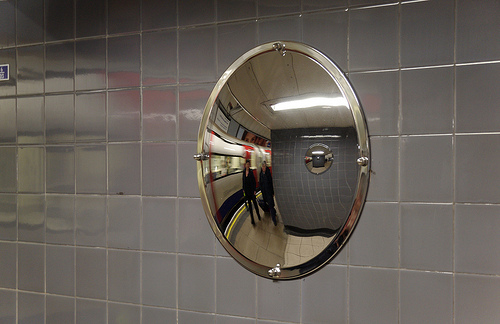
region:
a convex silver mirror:
[182, 35, 379, 284]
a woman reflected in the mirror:
[240, 152, 260, 233]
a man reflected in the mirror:
[258, 156, 280, 231]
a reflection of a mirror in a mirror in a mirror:
[301, 135, 341, 177]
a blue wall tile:
[91, 77, 150, 149]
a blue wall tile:
[397, 194, 459, 279]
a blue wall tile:
[71, 83, 106, 148]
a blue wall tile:
[95, 235, 150, 315]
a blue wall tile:
[7, 231, 53, 303]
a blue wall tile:
[338, 1, 410, 73]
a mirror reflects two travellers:
[193, 37, 373, 283]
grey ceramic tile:
[6, 90, 196, 318]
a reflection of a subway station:
[193, 37, 372, 282]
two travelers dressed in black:
[240, 157, 280, 225]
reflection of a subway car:
[196, 56, 243, 268]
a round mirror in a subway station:
[194, 39, 374, 282]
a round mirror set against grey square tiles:
[177, 27, 418, 305]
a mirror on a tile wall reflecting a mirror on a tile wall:
[266, 116, 371, 284]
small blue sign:
[0, 62, 7, 81]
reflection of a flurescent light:
[262, 92, 345, 110]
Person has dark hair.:
[241, 155, 252, 170]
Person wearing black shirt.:
[228, 168, 265, 191]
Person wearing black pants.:
[241, 196, 268, 230]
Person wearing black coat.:
[255, 180, 271, 185]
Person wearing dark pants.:
[261, 203, 284, 214]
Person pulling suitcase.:
[251, 189, 267, 216]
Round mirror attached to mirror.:
[210, 87, 324, 213]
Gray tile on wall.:
[402, 208, 461, 307]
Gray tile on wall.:
[351, 263, 392, 307]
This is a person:
[234, 147, 266, 233]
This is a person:
[257, 150, 277, 237]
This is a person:
[242, 152, 260, 233]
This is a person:
[258, 150, 288, 236]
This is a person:
[236, 152, 262, 244]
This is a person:
[235, 148, 270, 235]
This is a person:
[256, 150, 283, 243]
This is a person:
[260, 151, 282, 233]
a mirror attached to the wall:
[192, 40, 374, 285]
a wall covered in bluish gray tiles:
[1, 5, 497, 322]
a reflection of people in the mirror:
[243, 160, 278, 225]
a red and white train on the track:
[206, 133, 266, 210]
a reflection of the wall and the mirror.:
[266, 128, 356, 228]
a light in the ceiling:
[274, 92, 347, 119]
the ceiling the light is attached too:
[236, 59, 343, 135]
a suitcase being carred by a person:
[254, 194, 264, 211]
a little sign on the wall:
[1, 63, 11, 89]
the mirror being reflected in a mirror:
[300, 140, 332, 175]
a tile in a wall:
[13, 45, 44, 90]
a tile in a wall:
[42, 39, 76, 96]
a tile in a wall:
[71, 34, 110, 95]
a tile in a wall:
[101, 30, 143, 91]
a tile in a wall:
[133, 25, 179, 86]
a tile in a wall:
[176, 22, 216, 87]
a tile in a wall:
[213, 20, 254, 78]